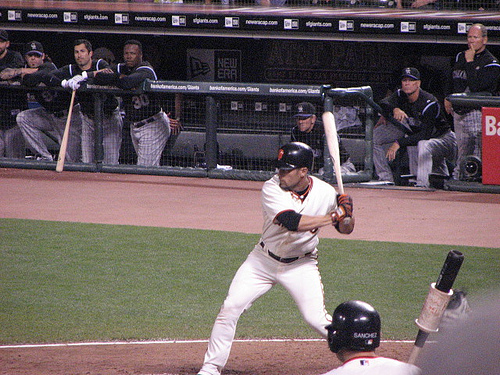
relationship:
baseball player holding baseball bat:
[193, 110, 353, 375] [317, 110, 355, 226]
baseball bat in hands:
[317, 110, 355, 226] [327, 189, 357, 224]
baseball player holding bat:
[326, 244, 463, 369] [404, 245, 466, 367]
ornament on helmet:
[277, 149, 283, 159] [272, 142, 314, 173]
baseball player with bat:
[193, 110, 353, 375] [320, 105, 356, 210]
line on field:
[3, 327, 209, 348] [1, 165, 497, 373]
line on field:
[234, 330, 323, 347] [1, 165, 497, 373]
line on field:
[380, 328, 415, 347] [1, 165, 497, 373]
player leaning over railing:
[11, 41, 73, 166] [4, 78, 373, 178]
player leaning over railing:
[59, 39, 122, 164] [4, 78, 373, 178]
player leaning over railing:
[94, 42, 170, 167] [4, 78, 373, 178]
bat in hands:
[53, 119, 70, 177] [63, 75, 87, 90]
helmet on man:
[260, 133, 382, 198] [190, 137, 353, 371]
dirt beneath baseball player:
[237, 346, 310, 372] [193, 110, 353, 375]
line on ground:
[234, 330, 323, 347] [1, 165, 498, 373]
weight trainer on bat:
[414, 282, 454, 333] [389, 245, 485, 372]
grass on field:
[4, 232, 211, 340] [1, 165, 497, 373]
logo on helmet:
[272, 147, 284, 161] [270, 144, 310, 170]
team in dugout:
[18, 43, 203, 161] [2, 9, 492, 192]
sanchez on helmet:
[352, 328, 380, 341] [321, 298, 384, 356]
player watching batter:
[0, 41, 61, 166] [191, 136, 353, 373]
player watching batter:
[59, 39, 122, 164] [191, 136, 353, 373]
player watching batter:
[94, 42, 170, 167] [191, 136, 353, 373]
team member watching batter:
[367, 64, 458, 186] [191, 136, 353, 373]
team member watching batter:
[448, 21, 499, 189] [191, 136, 353, 373]